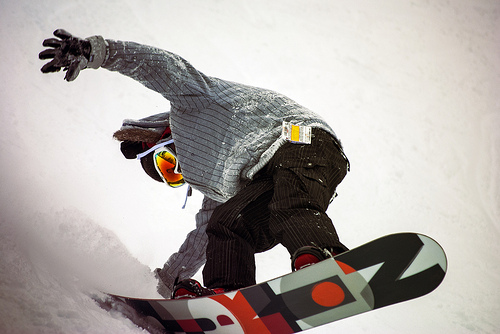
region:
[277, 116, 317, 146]
the snowboarded has credentials on his outfit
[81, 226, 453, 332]
snowboard dude's board is multicolored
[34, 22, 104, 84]
snowboard dude is wearing black gloves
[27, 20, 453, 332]
snowboard dude launching into the air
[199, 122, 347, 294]
snowboard dude's pants are dark brown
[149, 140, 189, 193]
snowboard dude is wearing reflective goggles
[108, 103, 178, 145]
snowboard dude's jacket has a hood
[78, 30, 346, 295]
snowboard dude's jacket is gray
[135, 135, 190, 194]
snowboard dude is wearing a helmet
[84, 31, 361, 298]
snowboard dude's outfit is striped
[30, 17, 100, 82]
a black glove on hand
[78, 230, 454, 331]
the snowboard is white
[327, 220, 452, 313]
the letter N on snowboard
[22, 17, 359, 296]
man wears black pants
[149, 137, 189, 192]
goggles are color orange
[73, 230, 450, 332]
snowboard has red, black and red decorations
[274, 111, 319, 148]
a tag on pants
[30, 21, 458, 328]
snowboarder is bend forward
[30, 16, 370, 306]
the snowboarder is crouched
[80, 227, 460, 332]
snow board flexing off snow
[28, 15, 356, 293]
snow boarder with snow gear on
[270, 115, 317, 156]
tag on jacket for snow time allowance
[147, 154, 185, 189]
mirror lens on snowboarders face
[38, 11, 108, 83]
snow gloves with white snow on them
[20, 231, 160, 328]
snow and end of snow board touching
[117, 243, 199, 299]
arm in snow and snow kicking up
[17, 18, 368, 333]
man doing a trick on a snowboard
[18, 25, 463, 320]
man doing tricks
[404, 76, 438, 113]
white clouds in blue sky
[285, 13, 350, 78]
white clouds in blue sky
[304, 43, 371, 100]
white clouds in blue sky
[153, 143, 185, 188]
Reflective goggles on a face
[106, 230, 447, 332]
Underside of a snowboard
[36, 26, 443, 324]
A man on a snowboard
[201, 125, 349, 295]
A pair of pants with pinstripes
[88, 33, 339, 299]
A gray shirt with pinstripes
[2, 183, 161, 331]
White fluffy snow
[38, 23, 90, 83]
A thick, black glove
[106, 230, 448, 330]
A snowboard in the snow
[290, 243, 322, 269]
The toe of a snow boot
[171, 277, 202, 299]
Toe of a snow boot